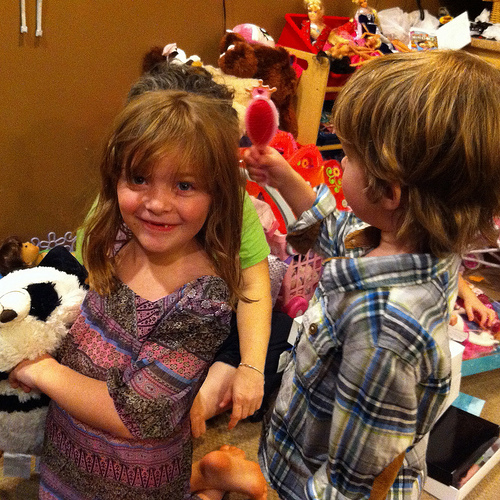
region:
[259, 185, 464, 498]
White, blue, gray, and green plaid shirt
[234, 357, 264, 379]
Bracelet on adult woman's left wrist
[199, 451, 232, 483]
Heel on foot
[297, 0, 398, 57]
3 Barbie dolls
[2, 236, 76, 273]
Doll in lying down position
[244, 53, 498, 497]
Boy holding hair brush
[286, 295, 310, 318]
Pink wheel to girl's toy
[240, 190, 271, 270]
Lime green tee shirt sleeve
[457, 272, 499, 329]
Disembodied hand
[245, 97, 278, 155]
a small pink brush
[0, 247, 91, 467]
a large black and white stuffed animal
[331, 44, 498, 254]
a boy's short cut hair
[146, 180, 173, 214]
the nose of a girl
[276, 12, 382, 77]
part of a red bin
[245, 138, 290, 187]
the hand of a boy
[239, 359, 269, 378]
a woman's bracelet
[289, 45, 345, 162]
part of a wooden shelf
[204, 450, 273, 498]
a barefoot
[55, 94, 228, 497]
This is a baby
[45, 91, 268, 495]
This is a baby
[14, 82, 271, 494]
this is a young girl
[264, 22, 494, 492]
this is a young boy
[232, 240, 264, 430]
this is a child's hand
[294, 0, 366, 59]
this is a doll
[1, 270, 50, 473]
this is a toy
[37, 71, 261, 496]
this child is kneeling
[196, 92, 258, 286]
this hair s long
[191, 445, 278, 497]
these are a child's feet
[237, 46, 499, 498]
little boy wearing plaid shirt holdinbg pink brush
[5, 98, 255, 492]
little girl with blond hair holding stuffed Panda toy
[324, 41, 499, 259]
little boy with blond hair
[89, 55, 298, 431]
woman wearing neon green shirt and silver bracelet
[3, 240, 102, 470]
black and white furry stuffed panda held by girl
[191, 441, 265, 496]
small bare feet with crossed ankles of little girl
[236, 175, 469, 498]
blue, black and grey plaid shirt on boy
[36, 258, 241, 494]
purple and pink paisley dress worn by girl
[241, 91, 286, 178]
small pink brush held by boy attempting to brush girl's hair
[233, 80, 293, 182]
boy holding pink and red lint brush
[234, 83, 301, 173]
boy holding pink and red lint brush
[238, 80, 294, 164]
boy holding pink and red lint brush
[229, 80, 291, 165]
boy holding pink and red lint brush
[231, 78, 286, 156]
boy holding pink and red lint brush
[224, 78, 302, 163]
boy holding pink and red lint brush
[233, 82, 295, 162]
boy holding pink and red lint brush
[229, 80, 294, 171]
boy holding pink and red lint brush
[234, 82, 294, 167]
boy holding pink and red lint brush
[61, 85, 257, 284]
girl smiling with brown hair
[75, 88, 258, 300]
girl smiling with brown hair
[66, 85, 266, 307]
girl smiling with brown hair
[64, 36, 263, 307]
girl smiling with brown hair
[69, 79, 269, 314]
girl smiling with brown hair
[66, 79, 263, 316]
girl smiling with brown hair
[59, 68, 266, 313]
girl smiling with brown hair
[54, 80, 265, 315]
girl smiling with brown hair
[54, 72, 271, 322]
girl smiling with brown hair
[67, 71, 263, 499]
a child playing inside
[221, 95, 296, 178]
a toy in the room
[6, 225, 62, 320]
a toy in the room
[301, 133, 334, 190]
a toy in the room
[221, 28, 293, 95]
a toy in the room